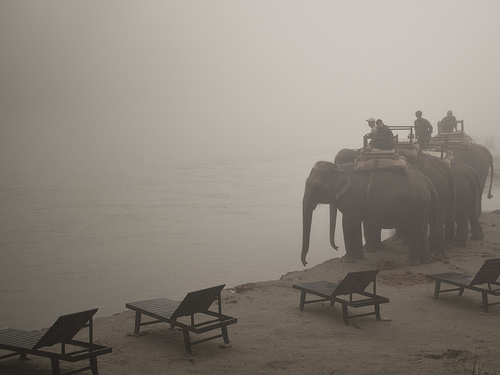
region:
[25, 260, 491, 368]
Four lawn chairs are on the beach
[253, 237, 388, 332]
The lawn chair is brown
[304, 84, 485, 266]
Four elephants stand near the shoreline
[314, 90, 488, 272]
The four elephants each have a rider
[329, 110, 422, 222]
The elephant is wearing a saddle made out of a strap, blanket, and a square wooden box with rails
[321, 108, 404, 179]
The man sits inside the wooden box with rails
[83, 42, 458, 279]
The elephants face the water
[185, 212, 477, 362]
The beach has wet, brown sand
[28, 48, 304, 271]
The water is still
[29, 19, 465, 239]
A fog drifts across the water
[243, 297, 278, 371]
this is the ground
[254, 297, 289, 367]
the ground is sandy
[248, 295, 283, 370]
the sand is brown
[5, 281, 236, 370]
these are several benches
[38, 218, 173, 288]
this is the water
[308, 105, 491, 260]
these are elephants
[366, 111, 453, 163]
several people on the elephants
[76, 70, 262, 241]
the water body is big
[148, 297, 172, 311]
the bench is wooden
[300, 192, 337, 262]
the trunks are long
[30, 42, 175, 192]
dark cloudy sea sky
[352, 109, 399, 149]
two men riding elephants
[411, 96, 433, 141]
one man on elephant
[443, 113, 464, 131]
one man on elephant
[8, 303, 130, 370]
one wooden beach chair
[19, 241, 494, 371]
four wooden beach chairs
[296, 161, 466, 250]
elephant walking on sand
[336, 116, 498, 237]
set of four elephants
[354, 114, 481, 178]
four men riding elephants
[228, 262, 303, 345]
edge of sand and ocean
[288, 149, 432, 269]
a very big elephant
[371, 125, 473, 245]
a very big elephant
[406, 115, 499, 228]
a very big elephant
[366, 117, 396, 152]
a man on an elephant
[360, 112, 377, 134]
a man on an elephant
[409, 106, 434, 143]
a man on an elephant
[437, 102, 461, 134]
a man on an elephant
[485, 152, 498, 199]
the tail of an elephant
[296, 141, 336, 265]
the head of an elephant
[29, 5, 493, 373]
elephants next to the water in the fog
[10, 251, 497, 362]
four beach chairs next to the water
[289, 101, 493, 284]
people riding elephants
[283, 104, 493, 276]
elephants next to the water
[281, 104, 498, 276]
riding elephants on the beach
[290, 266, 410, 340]
beach chair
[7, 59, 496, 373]
people and elephants at the beach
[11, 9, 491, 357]
foggy beach scene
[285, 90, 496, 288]
elephants in the fog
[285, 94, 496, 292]
people riding elephants in the fog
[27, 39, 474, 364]
fog in the air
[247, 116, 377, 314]
the elephants long trunk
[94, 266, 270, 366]
chairs on the ground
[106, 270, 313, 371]
wooden chairs on the ground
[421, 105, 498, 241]
the elephants long tail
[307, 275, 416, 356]
a chair ont he beach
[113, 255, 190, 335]
a chair ont he beach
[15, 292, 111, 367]
a chair ont he beach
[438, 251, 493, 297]
a chair ont he beach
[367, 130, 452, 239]
an elepahnt on the beach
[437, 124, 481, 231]
an elepahnt on the beach